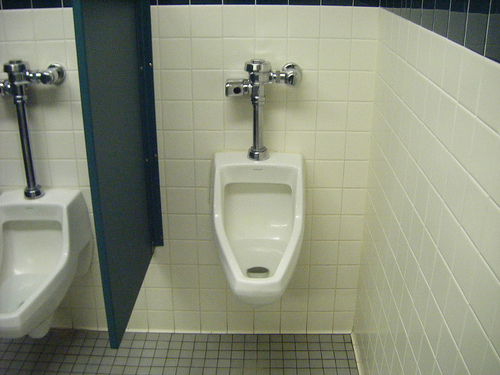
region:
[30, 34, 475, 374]
A men's bathroom with two urinals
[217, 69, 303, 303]
A higher up urinal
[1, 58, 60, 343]
A lower to the ground urinal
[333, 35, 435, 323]
White bathroom tyle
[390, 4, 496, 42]
Blue bathroom tile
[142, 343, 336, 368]
Small and grey floor tile for a bathroom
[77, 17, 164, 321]
Blue divider between urinals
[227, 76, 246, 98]
Automatic sensor on the higher urinal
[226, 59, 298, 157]
Silver flushing apparatus to the higher urinal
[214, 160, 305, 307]
Porcelain section to the higher urinal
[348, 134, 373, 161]
tile on back of wall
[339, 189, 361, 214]
tile on back of wall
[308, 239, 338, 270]
tile on back of wall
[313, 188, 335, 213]
tile on back of wall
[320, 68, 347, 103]
tile on back of wall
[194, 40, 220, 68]
tile on back of wall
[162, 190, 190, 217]
tile on back of wall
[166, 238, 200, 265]
tile on back of wall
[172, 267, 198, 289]
tile on back of wall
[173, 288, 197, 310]
tile on back of wall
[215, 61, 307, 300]
urinal on the right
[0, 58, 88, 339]
The urinal on the left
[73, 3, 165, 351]
the dark blue divider between the urinals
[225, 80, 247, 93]
motion censor on the right urinal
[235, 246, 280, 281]
water in the bottom of the right urinal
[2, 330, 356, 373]
gray tile floor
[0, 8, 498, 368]
white tile on the walls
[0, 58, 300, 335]
two urinals in the men's bathroom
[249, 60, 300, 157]
water pipe from wall into urinal for right urinal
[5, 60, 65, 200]
water pipes for left urinal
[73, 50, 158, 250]
Blue divider between urinals.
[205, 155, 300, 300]
White urinal attached to wall.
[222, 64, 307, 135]
Silver pipes on back or urinal.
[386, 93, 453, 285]
White tiles on wall in bathroom.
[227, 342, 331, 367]
Small gray tiles on floor in bathroom.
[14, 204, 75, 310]
White urinal attached to wall.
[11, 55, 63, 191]
Silver pipes attached to urinal in bathroom.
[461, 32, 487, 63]
Dark tiles around top of wall in room.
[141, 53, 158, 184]
Silver screws attached divider to wall.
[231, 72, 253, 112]
Urinal is automatic flusher.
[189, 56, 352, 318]
toilet hanging on the wall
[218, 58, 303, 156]
silver pipes attached to the wall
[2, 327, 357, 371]
small square tiles on the floor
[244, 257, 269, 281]
hole in the toilet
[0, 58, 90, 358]
toilet that is lower on the wall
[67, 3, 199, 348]
divider between the two toilets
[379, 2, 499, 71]
row of black tiles on the wall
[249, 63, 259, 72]
light shining on the silver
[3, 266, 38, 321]
water in the toilet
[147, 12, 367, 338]
cream tiles on the wall